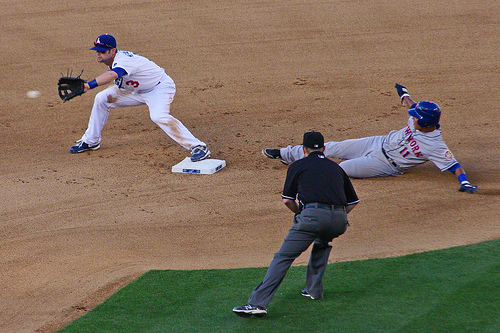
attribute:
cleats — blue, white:
[65, 136, 107, 157]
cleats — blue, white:
[185, 139, 215, 166]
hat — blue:
[82, 99, 157, 126]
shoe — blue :
[71, 139, 102, 151]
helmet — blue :
[411, 101, 441, 126]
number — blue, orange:
[392, 122, 425, 176]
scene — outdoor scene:
[5, 3, 496, 331]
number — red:
[120, 78, 150, 99]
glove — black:
[49, 65, 88, 100]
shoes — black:
[261, 141, 282, 160]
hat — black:
[296, 120, 326, 154]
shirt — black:
[280, 157, 370, 212]